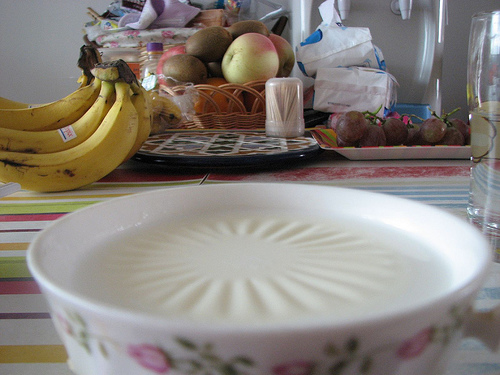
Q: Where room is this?
A: The kitchen.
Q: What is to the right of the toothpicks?
A: Stacked bags.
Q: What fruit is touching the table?
A: Bananas.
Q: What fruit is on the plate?
A: Grapes.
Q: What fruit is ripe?
A: Bananas.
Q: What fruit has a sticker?
A: The banana.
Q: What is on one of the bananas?
A: A brand name sticker.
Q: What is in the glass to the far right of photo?
A: Water.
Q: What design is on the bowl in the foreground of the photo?
A: Pink flowers with green leaves.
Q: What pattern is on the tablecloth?
A: Multi-colored stripes.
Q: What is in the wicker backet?
A: Apples and kiwi.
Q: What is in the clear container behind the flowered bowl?
A: Wooden toothpicks.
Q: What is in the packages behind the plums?
A: Wet wipes.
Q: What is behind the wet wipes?
A: A white plastic dispensing cooler.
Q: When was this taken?
A: Daytime.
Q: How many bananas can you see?
A: 4.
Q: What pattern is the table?
A: Striped.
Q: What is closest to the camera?
A: A bowl.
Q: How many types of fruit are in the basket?
A: 2.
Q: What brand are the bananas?
A: Dole.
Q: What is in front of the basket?
A: A plate.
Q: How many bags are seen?
A: 2.